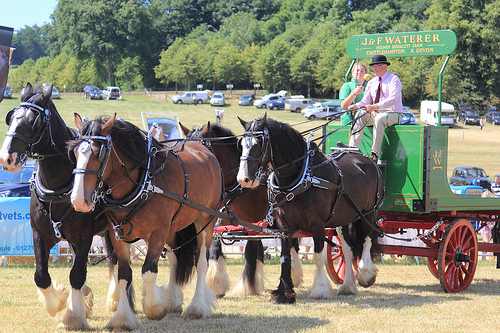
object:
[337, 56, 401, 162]
person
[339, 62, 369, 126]
person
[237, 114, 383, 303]
horse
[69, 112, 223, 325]
horse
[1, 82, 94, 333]
horse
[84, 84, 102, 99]
car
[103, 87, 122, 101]
car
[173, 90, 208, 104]
car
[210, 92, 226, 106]
car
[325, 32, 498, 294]
carriage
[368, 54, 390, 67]
hat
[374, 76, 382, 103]
tie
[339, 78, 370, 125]
shirt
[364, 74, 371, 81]
microphone top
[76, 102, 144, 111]
grass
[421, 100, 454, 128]
camper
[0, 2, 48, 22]
sky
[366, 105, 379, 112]
hand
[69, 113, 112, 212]
head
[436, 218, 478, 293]
wheel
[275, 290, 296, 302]
hoof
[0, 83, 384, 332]
horses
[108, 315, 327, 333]
shadow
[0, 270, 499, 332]
ground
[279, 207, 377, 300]
legs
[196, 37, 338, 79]
leaves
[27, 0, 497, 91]
trees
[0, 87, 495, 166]
field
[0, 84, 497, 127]
cars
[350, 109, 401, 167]
pants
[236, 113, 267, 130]
ears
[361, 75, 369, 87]
microphone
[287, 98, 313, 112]
van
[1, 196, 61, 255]
banner